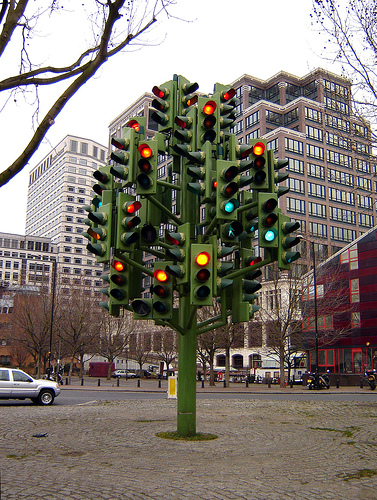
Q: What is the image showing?
A: It is showing a street.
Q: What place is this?
A: It is a street.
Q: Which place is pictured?
A: It is a street.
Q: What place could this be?
A: It is a street.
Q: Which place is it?
A: It is a street.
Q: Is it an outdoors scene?
A: Yes, it is outdoors.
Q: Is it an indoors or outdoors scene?
A: It is outdoors.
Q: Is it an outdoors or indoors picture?
A: It is outdoors.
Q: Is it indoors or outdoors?
A: It is outdoors.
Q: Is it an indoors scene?
A: No, it is outdoors.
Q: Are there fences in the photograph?
A: No, there are no fences.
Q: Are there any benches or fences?
A: No, there are no fences or benches.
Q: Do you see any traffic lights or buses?
A: Yes, there is a traffic light.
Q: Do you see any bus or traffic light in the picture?
A: Yes, there is a traffic light.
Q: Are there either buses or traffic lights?
A: Yes, there is a traffic light.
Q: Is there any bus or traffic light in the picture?
A: Yes, there is a traffic light.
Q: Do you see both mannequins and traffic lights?
A: No, there is a traffic light but no mannequins.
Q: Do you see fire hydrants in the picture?
A: No, there are no fire hydrants.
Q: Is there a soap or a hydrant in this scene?
A: No, there are no fire hydrants or soaps.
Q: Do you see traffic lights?
A: Yes, there is a traffic light.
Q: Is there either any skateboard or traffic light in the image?
A: Yes, there is a traffic light.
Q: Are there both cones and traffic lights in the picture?
A: No, there is a traffic light but no cones.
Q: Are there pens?
A: No, there are no pens.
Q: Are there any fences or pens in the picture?
A: No, there are no pens or fences.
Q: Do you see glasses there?
A: No, there are no glasses.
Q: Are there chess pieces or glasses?
A: No, there are no glasses or chess pieces.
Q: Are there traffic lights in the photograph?
A: Yes, there is a traffic light.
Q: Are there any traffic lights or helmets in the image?
A: Yes, there is a traffic light.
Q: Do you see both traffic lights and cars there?
A: Yes, there are both a traffic light and a car.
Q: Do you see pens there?
A: No, there are no pens.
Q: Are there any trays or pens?
A: No, there are no pens or trays.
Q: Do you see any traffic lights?
A: Yes, there is a traffic light.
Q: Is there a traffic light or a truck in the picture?
A: Yes, there is a traffic light.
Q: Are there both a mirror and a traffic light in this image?
A: No, there is a traffic light but no mirrors.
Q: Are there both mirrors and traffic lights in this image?
A: No, there is a traffic light but no mirrors.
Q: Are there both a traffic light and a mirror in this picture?
A: No, there is a traffic light but no mirrors.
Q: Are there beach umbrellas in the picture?
A: No, there are no beach umbrellas.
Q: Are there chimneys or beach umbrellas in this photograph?
A: No, there are no beach umbrellas or chimneys.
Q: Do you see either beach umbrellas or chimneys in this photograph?
A: No, there are no beach umbrellas or chimneys.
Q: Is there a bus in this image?
A: No, there are no buses.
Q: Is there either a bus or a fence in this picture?
A: No, there are no buses or fences.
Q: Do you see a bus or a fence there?
A: No, there are no buses or fences.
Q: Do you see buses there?
A: No, there are no buses.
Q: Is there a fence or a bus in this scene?
A: No, there are no buses or fences.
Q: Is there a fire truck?
A: No, there are no fire trucks.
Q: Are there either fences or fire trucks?
A: No, there are no fire trucks or fences.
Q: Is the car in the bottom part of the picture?
A: Yes, the car is in the bottom of the image.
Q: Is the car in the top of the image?
A: No, the car is in the bottom of the image.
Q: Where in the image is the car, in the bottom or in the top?
A: The car is in the bottom of the image.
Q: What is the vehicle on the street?
A: The vehicle is a car.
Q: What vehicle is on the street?
A: The vehicle is a car.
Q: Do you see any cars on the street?
A: Yes, there is a car on the street.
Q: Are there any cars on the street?
A: Yes, there is a car on the street.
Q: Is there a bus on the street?
A: No, there is a car on the street.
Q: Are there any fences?
A: No, there are no fences.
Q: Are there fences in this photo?
A: No, there are no fences.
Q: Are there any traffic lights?
A: Yes, there is a traffic light.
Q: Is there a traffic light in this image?
A: Yes, there is a traffic light.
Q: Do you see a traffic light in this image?
A: Yes, there is a traffic light.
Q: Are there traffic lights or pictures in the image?
A: Yes, there is a traffic light.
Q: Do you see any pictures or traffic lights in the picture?
A: Yes, there is a traffic light.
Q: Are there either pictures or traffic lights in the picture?
A: Yes, there is a traffic light.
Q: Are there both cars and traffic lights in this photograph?
A: Yes, there are both a traffic light and a car.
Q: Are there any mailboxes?
A: No, there are no mailboxes.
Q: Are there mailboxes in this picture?
A: No, there are no mailboxes.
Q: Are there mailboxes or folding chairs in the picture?
A: No, there are no mailboxes or folding chairs.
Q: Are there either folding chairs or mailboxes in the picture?
A: No, there are no mailboxes or folding chairs.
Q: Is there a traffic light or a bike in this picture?
A: Yes, there is a traffic light.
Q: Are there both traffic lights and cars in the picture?
A: Yes, there are both a traffic light and a car.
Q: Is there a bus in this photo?
A: No, there are no buses.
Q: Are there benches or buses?
A: No, there are no buses or benches.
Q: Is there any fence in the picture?
A: No, there are no fences.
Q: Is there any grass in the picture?
A: Yes, there is grass.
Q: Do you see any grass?
A: Yes, there is grass.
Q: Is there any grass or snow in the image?
A: Yes, there is grass.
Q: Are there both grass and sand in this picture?
A: No, there is grass but no sand.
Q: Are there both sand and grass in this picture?
A: No, there is grass but no sand.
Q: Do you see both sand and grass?
A: No, there is grass but no sand.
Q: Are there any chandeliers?
A: No, there are no chandeliers.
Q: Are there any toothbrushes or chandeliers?
A: No, there are no chandeliers or toothbrushes.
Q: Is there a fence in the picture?
A: No, there are no fences.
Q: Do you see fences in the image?
A: No, there are no fences.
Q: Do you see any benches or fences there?
A: No, there are no fences or benches.